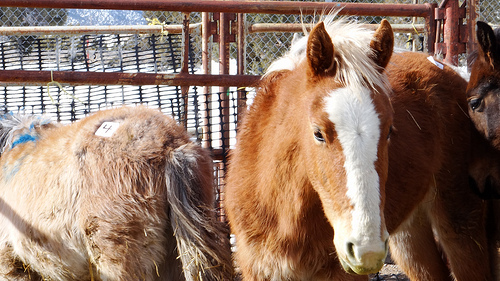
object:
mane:
[285, 2, 388, 93]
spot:
[7, 131, 37, 149]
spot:
[28, 116, 52, 128]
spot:
[6, 154, 27, 176]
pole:
[180, 13, 190, 130]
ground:
[423, 128, 453, 174]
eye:
[387, 124, 394, 139]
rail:
[1, 0, 500, 224]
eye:
[313, 128, 325, 142]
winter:
[0, 0, 499, 281]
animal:
[0, 100, 223, 281]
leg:
[82, 171, 175, 280]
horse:
[226, 17, 499, 281]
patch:
[323, 85, 385, 254]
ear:
[365, 18, 395, 75]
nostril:
[343, 240, 358, 262]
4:
[102, 124, 112, 134]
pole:
[0, 69, 256, 87]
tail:
[165, 130, 233, 281]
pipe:
[0, 25, 185, 37]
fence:
[1, 0, 500, 281]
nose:
[337, 227, 396, 274]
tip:
[350, 242, 386, 275]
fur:
[17, 130, 162, 259]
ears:
[304, 19, 342, 78]